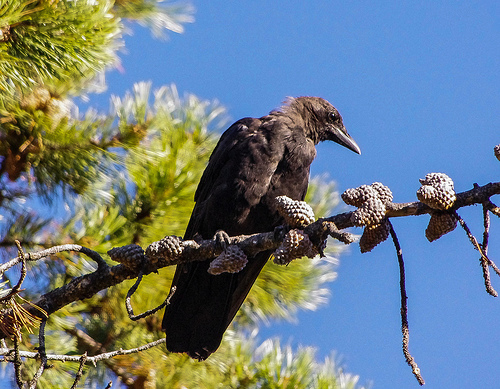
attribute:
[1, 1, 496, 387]
tree — green, pine tree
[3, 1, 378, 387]
leaves — white, green, pine needles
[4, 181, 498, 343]
branch — dead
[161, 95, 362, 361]
bird — black, large, grey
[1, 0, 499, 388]
sky — beautiful, blue, azure blue, clear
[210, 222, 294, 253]
feet — black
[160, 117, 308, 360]
wing — feathered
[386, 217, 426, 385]
twig — long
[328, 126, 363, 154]
beak — black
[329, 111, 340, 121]
eye — small, black, beady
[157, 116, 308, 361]
feathers — black